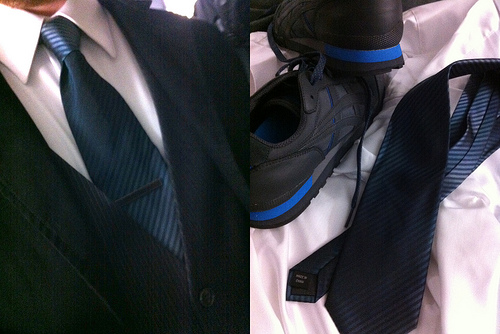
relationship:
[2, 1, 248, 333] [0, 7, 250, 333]
man has blazer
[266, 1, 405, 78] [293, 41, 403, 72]
shoe has heel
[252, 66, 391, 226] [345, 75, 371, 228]
shoe has lace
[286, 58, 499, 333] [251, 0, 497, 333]
tie laying on cloth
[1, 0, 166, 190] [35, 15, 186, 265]
shirt under tie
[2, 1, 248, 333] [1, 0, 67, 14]
man has chin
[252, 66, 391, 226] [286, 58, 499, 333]
shoe next to tie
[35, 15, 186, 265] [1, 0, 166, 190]
tie on top of shirt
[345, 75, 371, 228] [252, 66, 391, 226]
lace on top of shoe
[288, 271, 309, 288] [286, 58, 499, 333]
tag on top of tie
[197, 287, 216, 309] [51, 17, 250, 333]
button on top of blazer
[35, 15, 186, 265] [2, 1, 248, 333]
tie on top of man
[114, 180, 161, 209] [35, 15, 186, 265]
tie clip on top of tie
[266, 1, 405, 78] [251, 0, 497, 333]
shoe on top of cloth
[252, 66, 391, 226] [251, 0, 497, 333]
shoe on top of cloth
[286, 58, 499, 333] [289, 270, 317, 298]
tie has tip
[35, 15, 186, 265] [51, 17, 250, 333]
tie under blazer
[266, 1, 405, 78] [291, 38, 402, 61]
shoe has stripe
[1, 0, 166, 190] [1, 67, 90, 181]
shirt has wrinkle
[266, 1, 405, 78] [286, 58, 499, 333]
shoe next to tie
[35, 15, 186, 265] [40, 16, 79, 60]
tie has knot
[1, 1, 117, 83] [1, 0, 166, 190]
collar on top of shirt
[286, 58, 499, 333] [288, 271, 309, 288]
tie has tag